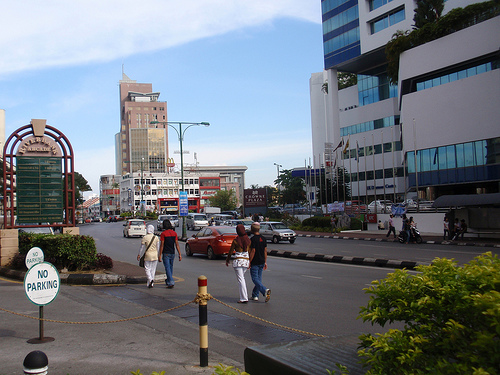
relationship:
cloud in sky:
[9, 12, 273, 65] [6, 1, 320, 144]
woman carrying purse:
[135, 221, 165, 283] [139, 256, 145, 264]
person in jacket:
[158, 215, 186, 289] [159, 229, 177, 254]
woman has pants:
[228, 224, 257, 303] [230, 263, 255, 302]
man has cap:
[244, 213, 274, 303] [251, 221, 261, 227]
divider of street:
[258, 239, 471, 284] [78, 221, 499, 349]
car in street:
[181, 222, 242, 260] [78, 221, 499, 349]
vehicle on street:
[121, 216, 148, 241] [78, 221, 499, 349]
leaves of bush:
[60, 240, 84, 249] [22, 229, 102, 270]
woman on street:
[222, 224, 257, 303] [78, 221, 499, 349]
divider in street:
[258, 239, 471, 284] [78, 221, 499, 349]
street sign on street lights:
[173, 190, 191, 217] [148, 117, 217, 239]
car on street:
[181, 222, 242, 260] [78, 221, 499, 349]